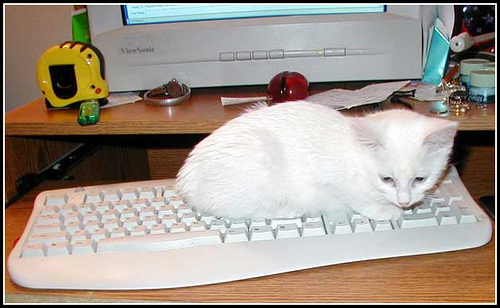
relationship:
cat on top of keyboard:
[174, 99, 461, 221] [44, 167, 173, 259]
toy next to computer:
[48, 51, 101, 112] [134, 7, 211, 33]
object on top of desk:
[148, 83, 182, 101] [163, 110, 203, 127]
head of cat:
[346, 120, 436, 207] [174, 99, 461, 221]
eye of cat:
[413, 172, 425, 184] [174, 99, 461, 221]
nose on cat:
[402, 199, 412, 205] [174, 99, 461, 221]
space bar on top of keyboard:
[120, 231, 204, 253] [44, 167, 173, 259]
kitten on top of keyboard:
[206, 111, 391, 212] [44, 167, 173, 259]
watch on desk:
[72, 100, 94, 127] [163, 110, 203, 127]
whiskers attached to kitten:
[369, 190, 388, 198] [206, 111, 391, 212]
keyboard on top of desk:
[44, 167, 173, 259] [163, 110, 203, 127]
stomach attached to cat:
[287, 193, 321, 219] [174, 99, 461, 221]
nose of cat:
[402, 199, 412, 205] [174, 99, 461, 221]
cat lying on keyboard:
[174, 99, 461, 221] [44, 167, 173, 259]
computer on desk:
[134, 7, 211, 33] [163, 110, 203, 127]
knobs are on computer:
[263, 53, 284, 63] [134, 7, 211, 33]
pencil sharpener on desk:
[46, 41, 88, 65] [163, 110, 203, 127]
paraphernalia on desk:
[50, 48, 294, 98] [163, 110, 203, 127]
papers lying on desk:
[308, 85, 381, 113] [163, 110, 203, 127]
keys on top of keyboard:
[107, 199, 156, 232] [44, 167, 173, 259]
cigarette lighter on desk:
[84, 105, 97, 113] [163, 110, 203, 127]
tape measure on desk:
[285, 87, 302, 101] [163, 110, 203, 127]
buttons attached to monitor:
[222, 54, 234, 62] [117, 0, 421, 75]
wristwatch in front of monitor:
[425, 93, 466, 117] [117, 0, 421, 75]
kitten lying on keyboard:
[206, 111, 391, 212] [44, 167, 173, 259]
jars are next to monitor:
[438, 31, 482, 81] [117, 0, 421, 75]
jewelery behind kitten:
[350, 90, 417, 111] [206, 111, 391, 212]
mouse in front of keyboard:
[283, 84, 314, 92] [44, 167, 173, 259]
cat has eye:
[178, 88, 446, 215] [379, 172, 403, 186]